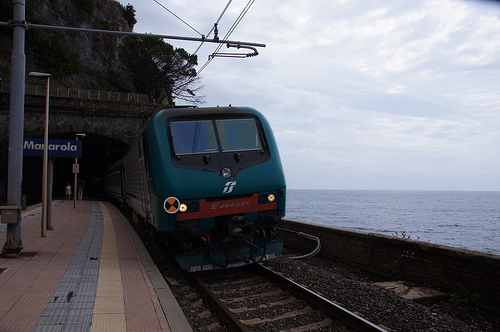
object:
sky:
[111, 1, 500, 193]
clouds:
[113, 0, 499, 191]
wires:
[153, 0, 206, 35]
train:
[89, 104, 288, 274]